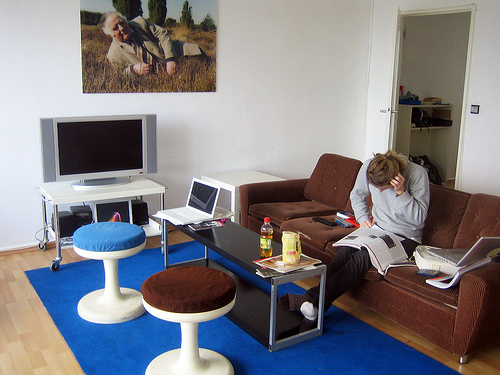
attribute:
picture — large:
[76, 15, 250, 84]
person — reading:
[341, 146, 442, 339]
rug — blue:
[37, 260, 73, 315]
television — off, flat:
[35, 112, 161, 185]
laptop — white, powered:
[156, 178, 223, 234]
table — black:
[152, 198, 333, 356]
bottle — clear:
[258, 214, 274, 268]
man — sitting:
[352, 143, 424, 285]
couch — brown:
[245, 147, 497, 364]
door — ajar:
[384, 7, 401, 156]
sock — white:
[301, 296, 319, 324]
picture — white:
[77, 5, 219, 98]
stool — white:
[139, 261, 250, 369]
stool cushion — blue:
[69, 217, 145, 255]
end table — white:
[205, 168, 280, 187]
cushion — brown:
[137, 265, 233, 303]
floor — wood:
[7, 261, 42, 371]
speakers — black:
[53, 203, 156, 236]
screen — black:
[59, 124, 138, 166]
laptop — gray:
[429, 232, 498, 291]